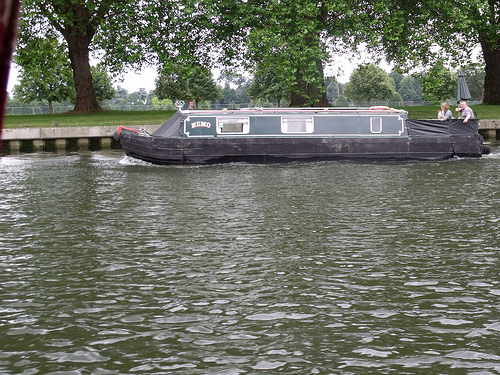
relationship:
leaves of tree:
[253, 20, 279, 56] [184, 5, 384, 97]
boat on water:
[107, 104, 487, 168] [0, 151, 498, 371]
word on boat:
[189, 119, 213, 128] [107, 104, 487, 168]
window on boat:
[279, 113, 317, 137] [107, 104, 487, 168]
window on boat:
[366, 118, 383, 136] [107, 104, 487, 168]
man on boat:
[455, 99, 475, 123] [107, 104, 487, 168]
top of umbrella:
[455, 66, 467, 76] [451, 65, 477, 103]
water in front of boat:
[0, 151, 498, 371] [107, 104, 487, 168]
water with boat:
[0, 151, 498, 371] [107, 104, 487, 168]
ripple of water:
[160, 175, 424, 215] [0, 151, 498, 371]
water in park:
[0, 151, 498, 371] [9, 99, 498, 124]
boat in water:
[107, 104, 487, 168] [0, 151, 498, 371]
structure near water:
[4, 129, 132, 148] [0, 151, 498, 371]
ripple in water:
[90, 166, 500, 315] [0, 151, 498, 371]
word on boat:
[207, 122, 212, 129] [107, 104, 487, 168]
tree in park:
[184, 5, 384, 97] [9, 99, 498, 124]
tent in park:
[451, 65, 477, 103] [9, 99, 498, 124]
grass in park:
[6, 114, 169, 128] [9, 99, 498, 124]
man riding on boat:
[455, 99, 475, 123] [107, 104, 487, 168]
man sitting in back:
[455, 99, 475, 123] [407, 116, 476, 141]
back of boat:
[407, 116, 476, 141] [107, 104, 487, 168]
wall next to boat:
[4, 129, 132, 148] [107, 104, 487, 168]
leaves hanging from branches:
[253, 20, 279, 56] [287, 9, 317, 85]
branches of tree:
[287, 9, 317, 85] [184, 5, 384, 97]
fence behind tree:
[2, 94, 478, 115] [246, 0, 335, 108]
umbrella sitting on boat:
[451, 65, 477, 103] [107, 104, 487, 168]